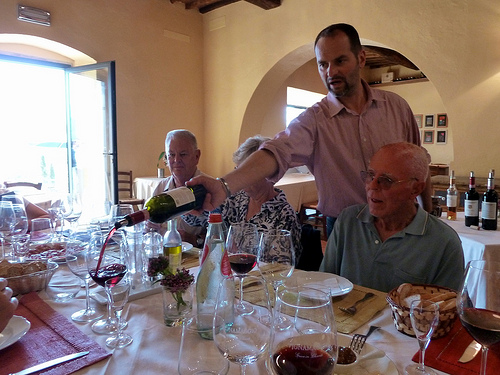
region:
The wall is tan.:
[217, 45, 247, 75]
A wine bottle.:
[110, 178, 208, 241]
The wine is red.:
[78, 252, 130, 289]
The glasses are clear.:
[206, 278, 359, 372]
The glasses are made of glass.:
[211, 269, 341, 374]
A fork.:
[336, 312, 386, 357]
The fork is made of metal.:
[340, 316, 386, 355]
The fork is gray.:
[347, 317, 387, 362]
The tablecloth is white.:
[136, 330, 166, 370]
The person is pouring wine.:
[96, 172, 226, 253]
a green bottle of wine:
[114, 185, 199, 235]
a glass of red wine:
[226, 221, 259, 315]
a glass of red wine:
[273, 287, 337, 373]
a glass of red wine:
[81, 225, 128, 333]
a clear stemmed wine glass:
[210, 273, 275, 371]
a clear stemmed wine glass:
[254, 227, 294, 329]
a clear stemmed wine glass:
[408, 299, 440, 371]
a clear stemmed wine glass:
[63, 234, 99, 324]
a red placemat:
[0, 294, 111, 373]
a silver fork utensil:
[346, 324, 377, 352]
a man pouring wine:
[71, 22, 379, 292]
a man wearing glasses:
[361, 133, 439, 242]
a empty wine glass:
[212, 254, 279, 373]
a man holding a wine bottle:
[163, 17, 380, 234]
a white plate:
[277, 266, 370, 296]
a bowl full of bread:
[388, 274, 453, 334]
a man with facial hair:
[310, 15, 375, 109]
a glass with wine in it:
[228, 211, 258, 274]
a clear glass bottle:
[183, 203, 236, 353]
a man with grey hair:
[359, 140, 431, 227]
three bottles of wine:
[443, 165, 498, 232]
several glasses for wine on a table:
[67, 228, 343, 363]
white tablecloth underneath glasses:
[63, 310, 260, 374]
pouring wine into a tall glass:
[88, 187, 195, 292]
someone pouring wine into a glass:
[208, 20, 402, 248]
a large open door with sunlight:
[22, 47, 129, 242]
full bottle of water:
[184, 213, 240, 371]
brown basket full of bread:
[6, 241, 61, 293]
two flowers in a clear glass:
[148, 252, 198, 322]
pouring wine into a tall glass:
[79, 212, 163, 338]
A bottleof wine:
[106, 188, 204, 230]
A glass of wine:
[90, 229, 137, 314]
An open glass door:
[63, 63, 112, 220]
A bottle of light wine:
[445, 169, 460, 218]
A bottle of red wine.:
[458, 166, 480, 233]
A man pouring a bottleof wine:
[116, 23, 424, 283]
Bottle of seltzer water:
[185, 213, 238, 340]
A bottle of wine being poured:
[86, 181, 226, 341]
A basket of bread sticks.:
[384, 279, 471, 341]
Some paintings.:
[423, 112, 453, 142]